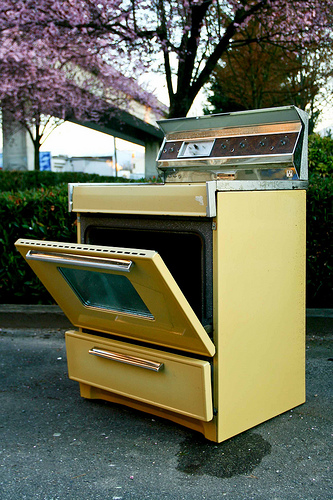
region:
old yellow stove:
[27, 84, 318, 443]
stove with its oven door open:
[0, 170, 268, 462]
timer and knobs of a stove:
[156, 121, 301, 175]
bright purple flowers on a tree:
[10, 11, 155, 173]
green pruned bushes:
[7, 150, 183, 338]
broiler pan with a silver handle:
[53, 329, 226, 438]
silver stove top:
[62, 154, 311, 216]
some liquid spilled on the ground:
[160, 397, 298, 477]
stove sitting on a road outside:
[9, 34, 330, 470]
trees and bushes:
[15, 11, 315, 285]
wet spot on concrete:
[173, 440, 284, 476]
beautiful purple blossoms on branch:
[15, 9, 145, 116]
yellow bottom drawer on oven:
[58, 330, 214, 419]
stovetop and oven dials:
[153, 136, 297, 156]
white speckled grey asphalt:
[3, 384, 27, 487]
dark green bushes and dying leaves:
[5, 182, 52, 227]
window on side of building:
[43, 129, 136, 177]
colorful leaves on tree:
[205, 34, 330, 115]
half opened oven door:
[50, 219, 208, 342]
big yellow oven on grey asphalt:
[28, 164, 321, 472]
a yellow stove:
[80, 128, 323, 444]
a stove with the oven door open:
[8, 200, 282, 370]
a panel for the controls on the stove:
[164, 135, 330, 170]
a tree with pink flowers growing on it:
[4, 4, 110, 176]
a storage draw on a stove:
[56, 318, 255, 444]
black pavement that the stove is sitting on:
[9, 388, 231, 478]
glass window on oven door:
[38, 257, 165, 332]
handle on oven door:
[22, 245, 155, 288]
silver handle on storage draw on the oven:
[78, 339, 177, 378]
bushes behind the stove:
[2, 186, 84, 304]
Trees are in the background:
[1, 1, 329, 181]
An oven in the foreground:
[14, 94, 327, 453]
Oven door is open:
[5, 209, 228, 363]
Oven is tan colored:
[9, 100, 332, 444]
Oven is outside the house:
[11, 96, 330, 454]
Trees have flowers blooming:
[2, 3, 143, 135]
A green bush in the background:
[2, 170, 332, 303]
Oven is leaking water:
[162, 420, 279, 490]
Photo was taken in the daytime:
[9, 5, 331, 498]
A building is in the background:
[3, 29, 163, 181]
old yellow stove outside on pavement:
[42, 72, 310, 424]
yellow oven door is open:
[4, 222, 223, 343]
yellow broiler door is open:
[51, 323, 227, 431]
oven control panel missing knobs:
[152, 130, 293, 161]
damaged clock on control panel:
[171, 137, 215, 159]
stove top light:
[150, 107, 306, 132]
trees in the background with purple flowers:
[9, 5, 318, 116]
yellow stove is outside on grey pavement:
[11, 317, 325, 479]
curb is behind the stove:
[6, 287, 61, 352]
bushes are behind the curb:
[7, 157, 57, 331]